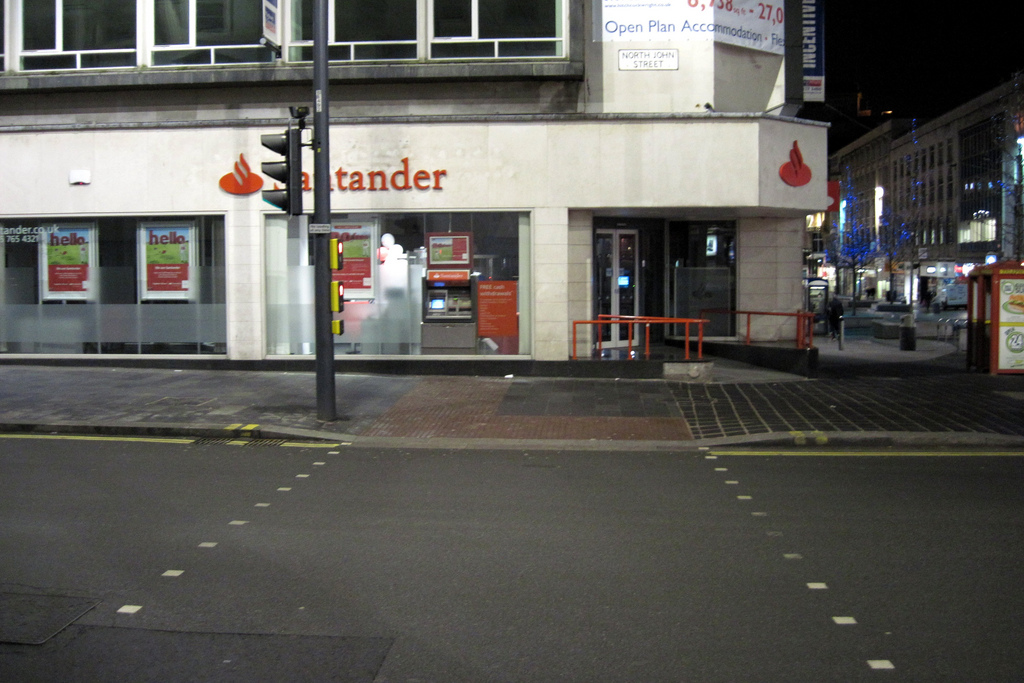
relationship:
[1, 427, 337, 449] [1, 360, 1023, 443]
line next to sidewalk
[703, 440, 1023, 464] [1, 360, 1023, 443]
line next to sidewalk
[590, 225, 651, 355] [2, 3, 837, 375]
doors to store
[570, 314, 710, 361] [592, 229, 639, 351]
railing on side of doors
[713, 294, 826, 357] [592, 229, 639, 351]
railing on side of doors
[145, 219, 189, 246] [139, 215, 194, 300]
hello written on poster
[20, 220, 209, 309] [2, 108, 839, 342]
signs in stote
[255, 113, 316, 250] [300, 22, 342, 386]
spotlight attached to a pole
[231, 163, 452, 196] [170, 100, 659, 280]
logo against background